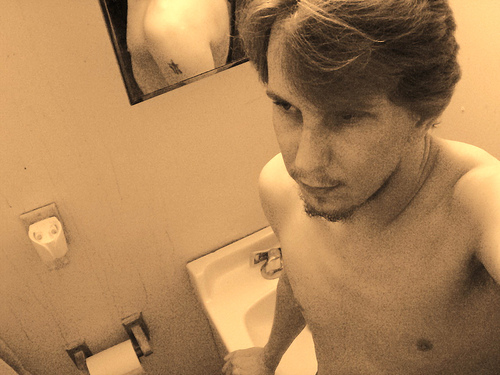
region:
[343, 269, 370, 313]
part of a chest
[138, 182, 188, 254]
part of a wall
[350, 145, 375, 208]
part of a cheek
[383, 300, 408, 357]
part of a chest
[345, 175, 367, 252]
part of a cheek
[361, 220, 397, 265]
part of a chest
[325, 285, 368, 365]
part of a chest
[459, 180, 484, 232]
part of a shoulder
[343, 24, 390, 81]
hair of a man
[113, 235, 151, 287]
part if a wall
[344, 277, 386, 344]
part of a chest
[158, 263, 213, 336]
part fo a wall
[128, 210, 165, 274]
part fo a wall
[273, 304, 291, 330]
aprt of a hand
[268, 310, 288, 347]
aprt of a hand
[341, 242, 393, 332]
part of a chest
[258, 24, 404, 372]
this is a man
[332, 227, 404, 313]
the man is light skinned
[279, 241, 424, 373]
the man is bare chested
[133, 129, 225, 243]
this is the wall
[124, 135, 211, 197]
the wall is white in color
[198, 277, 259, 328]
this is a sink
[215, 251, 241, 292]
the sink is white in color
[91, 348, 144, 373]
this is a tissue paper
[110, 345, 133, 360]
the tissue paper is white in color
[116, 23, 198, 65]
this is the image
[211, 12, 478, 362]
man in a bathroom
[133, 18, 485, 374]
man with no shirt on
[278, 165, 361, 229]
beard on man's face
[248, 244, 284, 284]
faucet next to the man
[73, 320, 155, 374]
toilet paper on a roll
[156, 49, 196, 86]
tattoo in a mirror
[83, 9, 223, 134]
mirror next to the man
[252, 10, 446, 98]
hair on man's head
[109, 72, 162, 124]
corner of the mirror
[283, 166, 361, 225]
dark hair mustache and goatee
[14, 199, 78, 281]
hand soap dispenser on wall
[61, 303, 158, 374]
toilet paper holder on a wall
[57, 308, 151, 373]
roll of toilet paper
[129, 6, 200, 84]
tattoo on upper arm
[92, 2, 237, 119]
reflection of shoulder in mirror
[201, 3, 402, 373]
man leaning on sink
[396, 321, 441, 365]
nipple on man's chest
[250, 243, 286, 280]
silver colored water tap handle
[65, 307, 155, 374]
roll of toilet tissue on a holder